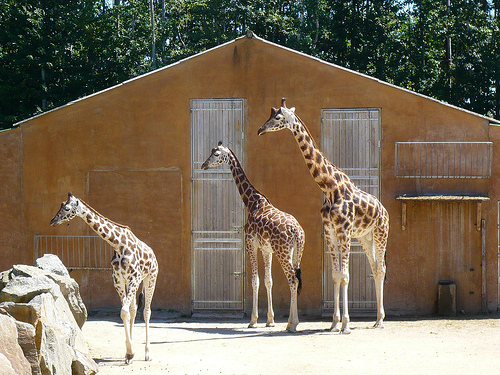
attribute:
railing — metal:
[392, 135, 496, 183]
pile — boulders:
[2, 250, 96, 374]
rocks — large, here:
[3, 245, 101, 374]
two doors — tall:
[183, 93, 391, 326]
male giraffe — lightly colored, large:
[253, 93, 403, 335]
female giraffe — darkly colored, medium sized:
[198, 135, 309, 335]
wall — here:
[38, 130, 482, 294]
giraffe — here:
[43, 186, 176, 368]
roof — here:
[10, 32, 493, 125]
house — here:
[4, 29, 499, 319]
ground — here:
[90, 309, 500, 373]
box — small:
[434, 272, 459, 320]